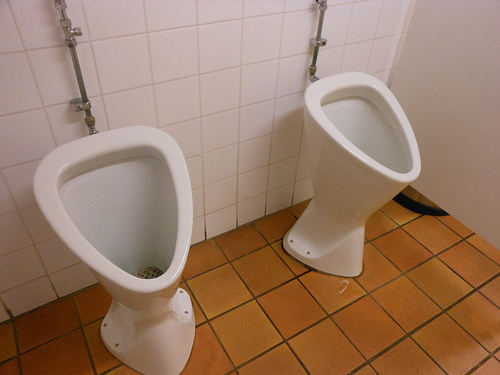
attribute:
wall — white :
[172, 1, 302, 151]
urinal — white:
[284, 66, 445, 203]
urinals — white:
[37, 87, 452, 325]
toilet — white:
[222, 27, 487, 291]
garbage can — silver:
[393, 186, 448, 216]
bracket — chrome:
[70, 94, 93, 116]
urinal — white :
[281, 70, 421, 276]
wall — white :
[388, 0, 498, 250]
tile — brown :
[216, 245, 294, 323]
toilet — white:
[281, 69, 417, 281]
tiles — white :
[106, 0, 282, 132]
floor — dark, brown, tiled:
[3, 190, 493, 373]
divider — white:
[386, 0, 498, 250]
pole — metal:
[40, 0, 115, 144]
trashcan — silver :
[392, 183, 451, 217]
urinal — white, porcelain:
[278, 66, 420, 295]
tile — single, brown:
[329, 287, 418, 358]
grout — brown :
[366, 268, 443, 325]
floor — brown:
[205, 239, 430, 373]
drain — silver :
[111, 232, 185, 304]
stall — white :
[381, 31, 498, 252]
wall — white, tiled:
[1, 0, 412, 325]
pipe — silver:
[54, 1, 96, 135]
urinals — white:
[56, 73, 458, 315]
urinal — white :
[292, 56, 399, 224]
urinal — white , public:
[32, 124, 195, 374]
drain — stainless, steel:
[131, 262, 163, 280]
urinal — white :
[23, 3, 212, 371]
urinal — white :
[254, 3, 429, 280]